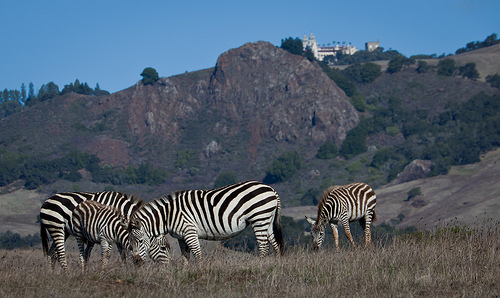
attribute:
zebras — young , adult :
[32, 177, 383, 270]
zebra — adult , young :
[33, 174, 381, 259]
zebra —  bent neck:
[121, 184, 291, 261]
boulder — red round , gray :
[195, 40, 360, 150]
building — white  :
[291, 21, 383, 71]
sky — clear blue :
[82, 7, 232, 30]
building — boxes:
[363, 37, 381, 51]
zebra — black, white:
[297, 179, 383, 262]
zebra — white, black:
[106, 178, 287, 269]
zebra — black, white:
[66, 190, 143, 276]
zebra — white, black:
[33, 189, 170, 282]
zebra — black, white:
[81, 191, 155, 228]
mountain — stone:
[14, 33, 372, 179]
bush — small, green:
[339, 119, 370, 163]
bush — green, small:
[262, 149, 312, 188]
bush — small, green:
[280, 35, 304, 55]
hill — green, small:
[24, 47, 472, 170]